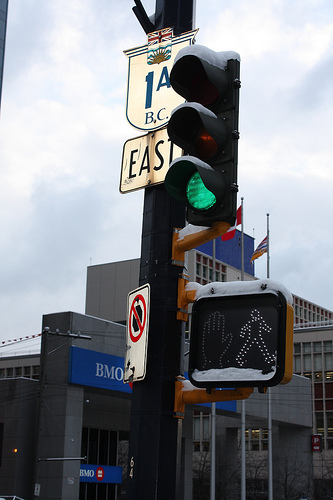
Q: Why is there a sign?
A: Notification.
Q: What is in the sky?
A: Clouds.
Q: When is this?
A: Daytime.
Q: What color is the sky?
A: Blue.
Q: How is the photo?
A: Clear.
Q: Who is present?
A: No one.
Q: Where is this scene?
A: At a traffic light.